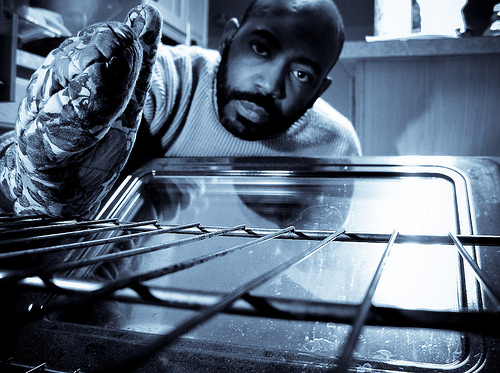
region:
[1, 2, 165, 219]
man wearing oven mitt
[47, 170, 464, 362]
glass in oven door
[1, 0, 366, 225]
man looking into oven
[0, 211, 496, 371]
black oven rack inside oven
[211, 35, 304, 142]
black beard on man's face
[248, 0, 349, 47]
balding head of man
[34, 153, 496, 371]
door of oven open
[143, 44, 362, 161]
man wearing ribbed sweater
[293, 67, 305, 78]
dark eye of man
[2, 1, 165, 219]
oven mitt on man's right hand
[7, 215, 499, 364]
the metal rack in the oven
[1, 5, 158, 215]
the oven mitt on the man's hand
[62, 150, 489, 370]
the oven door that is wide open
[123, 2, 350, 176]
the man looking into the oven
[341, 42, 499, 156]
the cabinet behind the man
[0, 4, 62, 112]
some stuff on the shelves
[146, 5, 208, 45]
part of the cabinet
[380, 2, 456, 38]
a window above the cabinet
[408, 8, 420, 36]
the sink faucet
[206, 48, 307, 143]
the man's beard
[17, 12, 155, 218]
Oven mitt worn by the man.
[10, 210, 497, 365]
The metal oven rack.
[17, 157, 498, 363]
The opened oven door.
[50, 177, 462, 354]
The glass window on the oven door.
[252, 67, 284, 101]
The man's nose.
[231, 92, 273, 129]
The lips of the man.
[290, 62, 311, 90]
The man's right eye.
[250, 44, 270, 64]
The man's left eye.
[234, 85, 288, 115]
The man's mustache.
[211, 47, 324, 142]
The man's beard and goatee.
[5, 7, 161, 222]
oven mit on right hand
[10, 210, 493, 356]
wire rack in oven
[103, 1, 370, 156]
man looking in oven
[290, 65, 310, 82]
left eye of man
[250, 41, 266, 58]
right eye of man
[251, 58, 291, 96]
nose of man looking in oven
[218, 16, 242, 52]
right ear of man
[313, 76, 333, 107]
left ear of man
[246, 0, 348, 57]
bald head of man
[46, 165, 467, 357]
glass on door of oven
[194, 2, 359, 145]
A man with a goatee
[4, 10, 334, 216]
Man wearing an oven mitt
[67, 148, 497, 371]
An open oven door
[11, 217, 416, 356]
An oven rack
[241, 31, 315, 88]
Eyes of a man looking in camera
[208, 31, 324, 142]
Mans face with facial hair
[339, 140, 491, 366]
Glare on an open oven glass door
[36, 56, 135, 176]
Patterns on an oven mitt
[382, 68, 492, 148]
Side panel on a cabinet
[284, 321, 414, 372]
Water marks on an oven glass door